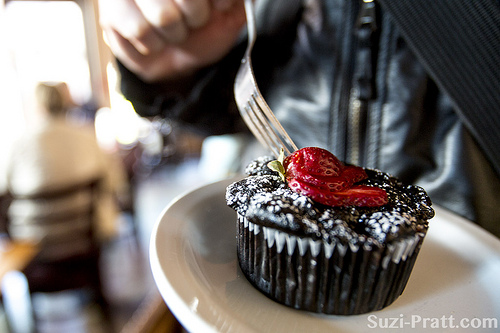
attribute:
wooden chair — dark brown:
[2, 178, 112, 328]